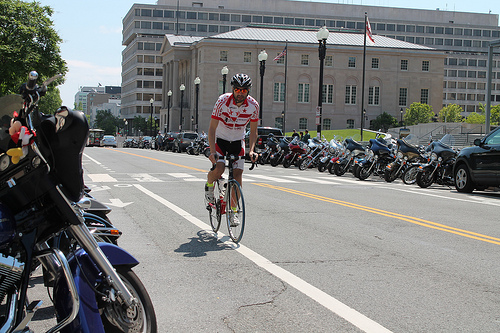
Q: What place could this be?
A: It is a road.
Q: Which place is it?
A: It is a road.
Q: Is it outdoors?
A: Yes, it is outdoors.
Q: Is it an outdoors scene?
A: Yes, it is outdoors.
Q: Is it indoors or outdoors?
A: It is outdoors.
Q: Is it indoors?
A: No, it is outdoors.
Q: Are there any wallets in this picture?
A: No, there are no wallets.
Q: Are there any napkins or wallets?
A: No, there are no wallets or napkins.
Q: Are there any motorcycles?
A: Yes, there is a motorcycle.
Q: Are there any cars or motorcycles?
A: Yes, there is a motorcycle.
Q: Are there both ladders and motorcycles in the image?
A: No, there is a motorcycle but no ladders.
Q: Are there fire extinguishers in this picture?
A: No, there are no fire extinguishers.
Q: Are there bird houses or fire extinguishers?
A: No, there are no fire extinguishers or bird houses.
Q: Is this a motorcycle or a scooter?
A: This is a motorcycle.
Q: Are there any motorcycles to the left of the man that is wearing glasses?
A: Yes, there is a motorcycle to the left of the man.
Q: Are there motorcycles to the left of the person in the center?
A: Yes, there is a motorcycle to the left of the man.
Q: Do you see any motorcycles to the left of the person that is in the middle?
A: Yes, there is a motorcycle to the left of the man.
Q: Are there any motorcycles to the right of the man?
A: No, the motorcycle is to the left of the man.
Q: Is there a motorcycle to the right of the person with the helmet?
A: No, the motorcycle is to the left of the man.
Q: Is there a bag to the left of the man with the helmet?
A: No, there is a motorcycle to the left of the man.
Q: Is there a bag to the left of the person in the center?
A: No, there is a motorcycle to the left of the man.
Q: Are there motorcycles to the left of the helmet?
A: Yes, there is a motorcycle to the left of the helmet.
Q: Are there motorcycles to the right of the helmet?
A: No, the motorcycle is to the left of the helmet.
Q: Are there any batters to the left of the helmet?
A: No, there is a motorcycle to the left of the helmet.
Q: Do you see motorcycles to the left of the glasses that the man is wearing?
A: Yes, there is a motorcycle to the left of the glasses.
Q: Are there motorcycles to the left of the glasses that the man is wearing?
A: Yes, there is a motorcycle to the left of the glasses.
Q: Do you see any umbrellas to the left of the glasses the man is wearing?
A: No, there is a motorcycle to the left of the glasses.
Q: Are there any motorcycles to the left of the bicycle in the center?
A: Yes, there is a motorcycle to the left of the bicycle.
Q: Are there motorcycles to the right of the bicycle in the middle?
A: No, the motorcycle is to the left of the bicycle.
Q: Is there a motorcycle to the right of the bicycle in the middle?
A: No, the motorcycle is to the left of the bicycle.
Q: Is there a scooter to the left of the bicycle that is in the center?
A: No, there is a motorcycle to the left of the bicycle.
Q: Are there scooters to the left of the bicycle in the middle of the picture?
A: No, there is a motorcycle to the left of the bicycle.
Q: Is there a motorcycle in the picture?
A: Yes, there is a motorcycle.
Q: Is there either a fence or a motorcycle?
A: Yes, there is a motorcycle.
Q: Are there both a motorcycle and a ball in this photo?
A: No, there is a motorcycle but no balls.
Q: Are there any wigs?
A: No, there are no wigs.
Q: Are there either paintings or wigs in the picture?
A: No, there are no wigs or paintings.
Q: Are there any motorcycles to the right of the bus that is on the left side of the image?
A: Yes, there is a motorcycle to the right of the bus.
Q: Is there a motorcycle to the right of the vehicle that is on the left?
A: Yes, there is a motorcycle to the right of the bus.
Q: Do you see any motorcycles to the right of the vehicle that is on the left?
A: Yes, there is a motorcycle to the right of the bus.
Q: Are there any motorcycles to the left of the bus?
A: No, the motorcycle is to the right of the bus.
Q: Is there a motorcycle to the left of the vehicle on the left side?
A: No, the motorcycle is to the right of the bus.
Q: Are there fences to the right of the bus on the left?
A: No, there is a motorcycle to the right of the bus.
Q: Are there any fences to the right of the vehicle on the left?
A: No, there is a motorcycle to the right of the bus.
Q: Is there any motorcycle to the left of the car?
A: Yes, there is a motorcycle to the left of the car.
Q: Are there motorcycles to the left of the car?
A: Yes, there is a motorcycle to the left of the car.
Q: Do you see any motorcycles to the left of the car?
A: Yes, there is a motorcycle to the left of the car.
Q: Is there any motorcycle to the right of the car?
A: No, the motorcycle is to the left of the car.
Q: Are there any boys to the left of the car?
A: No, there is a motorcycle to the left of the car.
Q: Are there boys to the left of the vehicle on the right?
A: No, there is a motorcycle to the left of the car.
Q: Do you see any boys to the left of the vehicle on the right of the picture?
A: No, there is a motorcycle to the left of the car.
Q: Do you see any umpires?
A: No, there are no umpires.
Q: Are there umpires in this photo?
A: No, there are no umpires.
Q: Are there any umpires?
A: No, there are no umpires.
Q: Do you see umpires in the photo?
A: No, there are no umpires.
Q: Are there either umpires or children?
A: No, there are no umpires or children.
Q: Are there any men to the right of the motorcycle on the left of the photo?
A: Yes, there is a man to the right of the motorbike.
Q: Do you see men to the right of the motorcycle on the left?
A: Yes, there is a man to the right of the motorbike.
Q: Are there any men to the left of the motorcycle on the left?
A: No, the man is to the right of the motorcycle.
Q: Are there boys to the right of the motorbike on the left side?
A: No, there is a man to the right of the motorcycle.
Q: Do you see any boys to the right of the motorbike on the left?
A: No, there is a man to the right of the motorcycle.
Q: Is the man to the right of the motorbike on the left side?
A: Yes, the man is to the right of the motorcycle.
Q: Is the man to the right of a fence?
A: No, the man is to the right of the motorcycle.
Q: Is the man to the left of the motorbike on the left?
A: No, the man is to the right of the motorbike.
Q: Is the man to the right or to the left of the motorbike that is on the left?
A: The man is to the right of the motorbike.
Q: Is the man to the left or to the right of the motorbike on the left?
A: The man is to the right of the motorbike.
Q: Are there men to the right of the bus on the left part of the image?
A: Yes, there is a man to the right of the bus.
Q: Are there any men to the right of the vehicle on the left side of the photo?
A: Yes, there is a man to the right of the bus.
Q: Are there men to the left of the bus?
A: No, the man is to the right of the bus.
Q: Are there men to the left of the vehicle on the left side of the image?
A: No, the man is to the right of the bus.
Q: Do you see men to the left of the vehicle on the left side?
A: No, the man is to the right of the bus.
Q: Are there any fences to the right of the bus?
A: No, there is a man to the right of the bus.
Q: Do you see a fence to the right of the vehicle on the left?
A: No, there is a man to the right of the bus.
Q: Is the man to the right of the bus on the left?
A: Yes, the man is to the right of the bus.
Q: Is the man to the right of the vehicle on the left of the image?
A: Yes, the man is to the right of the bus.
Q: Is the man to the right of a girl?
A: No, the man is to the right of the bus.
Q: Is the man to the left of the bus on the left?
A: No, the man is to the right of the bus.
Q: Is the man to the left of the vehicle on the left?
A: No, the man is to the right of the bus.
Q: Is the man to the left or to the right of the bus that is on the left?
A: The man is to the right of the bus.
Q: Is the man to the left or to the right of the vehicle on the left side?
A: The man is to the right of the bus.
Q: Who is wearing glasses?
A: The man is wearing glasses.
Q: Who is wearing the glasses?
A: The man is wearing glasses.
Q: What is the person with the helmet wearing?
A: The man is wearing glasses.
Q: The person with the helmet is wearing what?
A: The man is wearing glasses.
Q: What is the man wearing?
A: The man is wearing glasses.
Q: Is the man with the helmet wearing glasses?
A: Yes, the man is wearing glasses.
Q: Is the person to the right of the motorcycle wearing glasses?
A: Yes, the man is wearing glasses.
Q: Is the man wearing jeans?
A: No, the man is wearing glasses.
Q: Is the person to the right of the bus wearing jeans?
A: No, the man is wearing glasses.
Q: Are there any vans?
A: No, there are no vans.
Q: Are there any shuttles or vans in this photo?
A: No, there are no vans or shuttles.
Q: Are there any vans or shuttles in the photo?
A: No, there are no vans or shuttles.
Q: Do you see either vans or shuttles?
A: No, there are no vans or shuttles.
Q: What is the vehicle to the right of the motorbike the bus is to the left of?
A: The vehicle is a car.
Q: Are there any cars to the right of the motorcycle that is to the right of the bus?
A: Yes, there is a car to the right of the motorcycle.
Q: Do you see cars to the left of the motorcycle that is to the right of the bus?
A: No, the car is to the right of the motorcycle.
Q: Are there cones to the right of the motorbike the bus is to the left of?
A: No, there is a car to the right of the motorcycle.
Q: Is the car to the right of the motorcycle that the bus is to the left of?
A: Yes, the car is to the right of the motorbike.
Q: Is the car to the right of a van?
A: No, the car is to the right of the motorbike.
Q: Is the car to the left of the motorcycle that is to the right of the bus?
A: No, the car is to the right of the motorbike.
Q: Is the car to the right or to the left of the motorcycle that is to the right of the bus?
A: The car is to the right of the motorbike.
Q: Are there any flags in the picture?
A: Yes, there is a flag.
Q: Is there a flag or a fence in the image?
A: Yes, there is a flag.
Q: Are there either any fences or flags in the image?
A: Yes, there is a flag.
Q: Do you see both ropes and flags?
A: No, there is a flag but no ropes.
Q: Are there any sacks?
A: No, there are no sacks.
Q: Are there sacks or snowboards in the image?
A: No, there are no sacks or snowboards.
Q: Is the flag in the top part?
A: Yes, the flag is in the top of the image.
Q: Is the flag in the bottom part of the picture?
A: No, the flag is in the top of the image.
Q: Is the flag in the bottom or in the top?
A: The flag is in the top of the image.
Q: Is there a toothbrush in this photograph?
A: No, there are no toothbrushes.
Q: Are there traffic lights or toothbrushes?
A: No, there are no toothbrushes or traffic lights.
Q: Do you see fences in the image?
A: No, there are no fences.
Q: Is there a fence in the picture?
A: No, there are no fences.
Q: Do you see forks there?
A: Yes, there is a fork.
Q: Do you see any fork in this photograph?
A: Yes, there is a fork.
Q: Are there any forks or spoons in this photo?
A: Yes, there is a fork.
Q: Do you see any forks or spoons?
A: Yes, there is a fork.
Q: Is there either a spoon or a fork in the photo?
A: Yes, there is a fork.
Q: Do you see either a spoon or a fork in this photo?
A: Yes, there is a fork.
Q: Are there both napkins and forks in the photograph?
A: No, there is a fork but no napkins.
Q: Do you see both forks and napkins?
A: No, there is a fork but no napkins.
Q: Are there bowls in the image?
A: No, there are no bowls.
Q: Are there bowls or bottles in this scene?
A: No, there are no bowls or bottles.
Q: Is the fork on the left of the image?
A: Yes, the fork is on the left of the image.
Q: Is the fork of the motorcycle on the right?
A: No, the fork is on the left of the image.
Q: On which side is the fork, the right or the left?
A: The fork is on the left of the image.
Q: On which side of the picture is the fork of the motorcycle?
A: The fork is on the left of the image.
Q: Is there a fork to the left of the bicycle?
A: Yes, there is a fork to the left of the bicycle.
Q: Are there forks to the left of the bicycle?
A: Yes, there is a fork to the left of the bicycle.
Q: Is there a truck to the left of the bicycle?
A: No, there is a fork to the left of the bicycle.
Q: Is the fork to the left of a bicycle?
A: Yes, the fork is to the left of a bicycle.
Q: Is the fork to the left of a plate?
A: No, the fork is to the left of a bicycle.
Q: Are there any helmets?
A: Yes, there is a helmet.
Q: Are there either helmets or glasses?
A: Yes, there is a helmet.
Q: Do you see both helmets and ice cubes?
A: No, there is a helmet but no ice cubes.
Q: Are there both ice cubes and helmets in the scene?
A: No, there is a helmet but no ice cubes.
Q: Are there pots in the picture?
A: No, there are no pots.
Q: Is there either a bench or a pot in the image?
A: No, there are no pots or benches.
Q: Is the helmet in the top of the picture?
A: Yes, the helmet is in the top of the image.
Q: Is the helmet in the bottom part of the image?
A: No, the helmet is in the top of the image.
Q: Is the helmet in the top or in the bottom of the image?
A: The helmet is in the top of the image.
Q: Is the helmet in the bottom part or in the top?
A: The helmet is in the top of the image.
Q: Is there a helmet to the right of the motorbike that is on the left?
A: Yes, there is a helmet to the right of the motorbike.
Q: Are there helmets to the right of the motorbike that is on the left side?
A: Yes, there is a helmet to the right of the motorbike.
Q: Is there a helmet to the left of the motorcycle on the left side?
A: No, the helmet is to the right of the motorbike.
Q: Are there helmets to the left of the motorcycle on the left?
A: No, the helmet is to the right of the motorbike.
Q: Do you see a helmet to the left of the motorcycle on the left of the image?
A: No, the helmet is to the right of the motorbike.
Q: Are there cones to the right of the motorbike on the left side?
A: No, there is a helmet to the right of the motorcycle.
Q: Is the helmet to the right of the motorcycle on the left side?
A: Yes, the helmet is to the right of the motorbike.